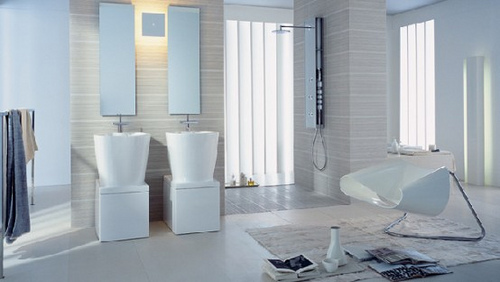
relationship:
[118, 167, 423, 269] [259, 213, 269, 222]
floor has a part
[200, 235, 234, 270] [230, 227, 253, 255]
white floor has a part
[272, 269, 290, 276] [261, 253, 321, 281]
part of a book